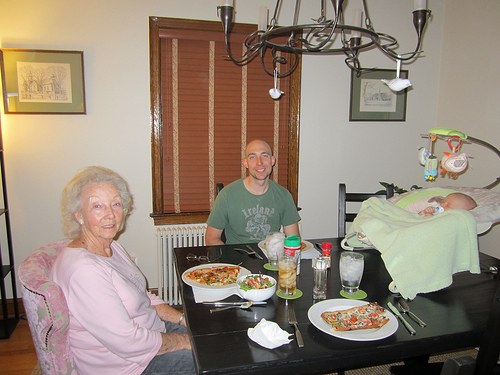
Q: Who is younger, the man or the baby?
A: The baby is younger than the man.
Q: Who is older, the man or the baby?
A: The man is older than the baby.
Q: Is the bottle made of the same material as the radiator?
A: No, the bottle is made of plastic and the radiator is made of metal.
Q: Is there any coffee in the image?
A: No, there is no coffee.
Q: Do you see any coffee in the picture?
A: No, there is no coffee.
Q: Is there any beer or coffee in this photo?
A: No, there are no coffee or beer.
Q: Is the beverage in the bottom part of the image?
A: Yes, the beverage is in the bottom of the image.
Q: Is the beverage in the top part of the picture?
A: No, the beverage is in the bottom of the image.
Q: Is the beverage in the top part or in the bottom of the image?
A: The beverage is in the bottom of the image.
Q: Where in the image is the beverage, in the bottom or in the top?
A: The beverage is in the bottom of the image.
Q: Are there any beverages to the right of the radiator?
A: Yes, there is a beverage to the right of the radiator.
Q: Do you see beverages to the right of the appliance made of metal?
A: Yes, there is a beverage to the right of the radiator.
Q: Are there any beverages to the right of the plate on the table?
A: Yes, there is a beverage to the right of the plate.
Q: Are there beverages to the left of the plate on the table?
A: No, the beverage is to the right of the plate.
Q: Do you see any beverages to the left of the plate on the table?
A: No, the beverage is to the right of the plate.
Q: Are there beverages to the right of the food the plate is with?
A: Yes, there is a beverage to the right of the food.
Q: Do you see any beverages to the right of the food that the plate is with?
A: Yes, there is a beverage to the right of the food.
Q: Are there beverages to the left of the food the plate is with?
A: No, the beverage is to the right of the food.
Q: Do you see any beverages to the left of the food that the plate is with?
A: No, the beverage is to the right of the food.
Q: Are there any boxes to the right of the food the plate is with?
A: No, there is a beverage to the right of the food.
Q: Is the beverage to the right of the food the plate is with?
A: Yes, the beverage is to the right of the food.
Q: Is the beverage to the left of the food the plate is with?
A: No, the beverage is to the right of the food.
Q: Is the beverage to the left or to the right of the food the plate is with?
A: The beverage is to the right of the food.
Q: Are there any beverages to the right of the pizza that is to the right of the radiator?
A: Yes, there is a beverage to the right of the pizza.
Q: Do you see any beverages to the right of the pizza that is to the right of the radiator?
A: Yes, there is a beverage to the right of the pizza.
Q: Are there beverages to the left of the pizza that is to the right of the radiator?
A: No, the beverage is to the right of the pizza.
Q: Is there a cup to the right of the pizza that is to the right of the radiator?
A: No, there is a beverage to the right of the pizza.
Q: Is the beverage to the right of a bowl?
A: Yes, the beverage is to the right of a bowl.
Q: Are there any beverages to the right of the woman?
A: Yes, there is a beverage to the right of the woman.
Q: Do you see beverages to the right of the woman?
A: Yes, there is a beverage to the right of the woman.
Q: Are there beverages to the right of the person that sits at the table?
A: Yes, there is a beverage to the right of the woman.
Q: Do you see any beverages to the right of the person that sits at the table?
A: Yes, there is a beverage to the right of the woman.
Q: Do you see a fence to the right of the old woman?
A: No, there is a beverage to the right of the woman.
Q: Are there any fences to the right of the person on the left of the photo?
A: No, there is a beverage to the right of the woman.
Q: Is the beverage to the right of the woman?
A: Yes, the beverage is to the right of the woman.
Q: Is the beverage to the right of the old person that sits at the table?
A: Yes, the beverage is to the right of the woman.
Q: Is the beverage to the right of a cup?
A: No, the beverage is to the right of the woman.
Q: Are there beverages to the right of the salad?
A: Yes, there is a beverage to the right of the salad.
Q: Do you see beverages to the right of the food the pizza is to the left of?
A: Yes, there is a beverage to the right of the salad.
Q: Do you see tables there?
A: Yes, there is a table.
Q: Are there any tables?
A: Yes, there is a table.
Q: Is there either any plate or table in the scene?
A: Yes, there is a table.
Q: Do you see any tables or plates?
A: Yes, there is a table.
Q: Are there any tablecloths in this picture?
A: No, there are no tablecloths.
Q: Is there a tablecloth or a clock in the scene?
A: No, there are no tablecloths or clocks.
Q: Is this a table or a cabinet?
A: This is a table.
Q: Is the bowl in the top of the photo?
A: No, the bowl is in the bottom of the image.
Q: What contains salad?
A: The bowl contains salad.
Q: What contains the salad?
A: The bowl contains salad.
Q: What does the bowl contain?
A: The bowl contains salad.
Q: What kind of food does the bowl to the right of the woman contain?
A: The bowl contains salad.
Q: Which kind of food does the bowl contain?
A: The bowl contains salad.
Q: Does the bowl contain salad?
A: Yes, the bowl contains salad.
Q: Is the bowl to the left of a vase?
A: No, the bowl is to the left of a beverage.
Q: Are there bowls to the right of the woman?
A: Yes, there is a bowl to the right of the woman.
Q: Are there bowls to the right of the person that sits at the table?
A: Yes, there is a bowl to the right of the woman.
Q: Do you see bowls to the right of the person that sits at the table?
A: Yes, there is a bowl to the right of the woman.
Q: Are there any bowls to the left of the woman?
A: No, the bowl is to the right of the woman.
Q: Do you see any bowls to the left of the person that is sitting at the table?
A: No, the bowl is to the right of the woman.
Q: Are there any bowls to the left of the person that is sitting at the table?
A: No, the bowl is to the right of the woman.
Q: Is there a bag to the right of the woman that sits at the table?
A: No, there is a bowl to the right of the woman.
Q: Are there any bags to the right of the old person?
A: No, there is a bowl to the right of the woman.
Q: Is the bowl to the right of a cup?
A: No, the bowl is to the right of the woman.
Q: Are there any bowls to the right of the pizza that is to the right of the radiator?
A: Yes, there is a bowl to the right of the pizza.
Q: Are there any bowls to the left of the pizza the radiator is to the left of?
A: No, the bowl is to the right of the pizza.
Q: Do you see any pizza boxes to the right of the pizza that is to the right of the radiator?
A: No, there is a bowl to the right of the pizza.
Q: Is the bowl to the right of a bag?
A: No, the bowl is to the right of the pizza.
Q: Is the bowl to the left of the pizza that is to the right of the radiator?
A: No, the bowl is to the right of the pizza.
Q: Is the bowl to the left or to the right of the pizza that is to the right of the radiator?
A: The bowl is to the right of the pizza.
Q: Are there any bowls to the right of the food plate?
A: Yes, there is a bowl to the right of the plate.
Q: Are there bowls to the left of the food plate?
A: No, the bowl is to the right of the plate.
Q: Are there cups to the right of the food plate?
A: No, there is a bowl to the right of the plate.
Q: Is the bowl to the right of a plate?
A: Yes, the bowl is to the right of a plate.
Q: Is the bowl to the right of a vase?
A: No, the bowl is to the right of a plate.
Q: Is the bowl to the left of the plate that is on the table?
A: No, the bowl is to the right of the plate.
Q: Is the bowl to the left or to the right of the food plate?
A: The bowl is to the right of the plate.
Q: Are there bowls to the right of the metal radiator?
A: Yes, there is a bowl to the right of the radiator.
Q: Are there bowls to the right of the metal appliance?
A: Yes, there is a bowl to the right of the radiator.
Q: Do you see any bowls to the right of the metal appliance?
A: Yes, there is a bowl to the right of the radiator.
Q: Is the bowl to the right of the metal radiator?
A: Yes, the bowl is to the right of the radiator.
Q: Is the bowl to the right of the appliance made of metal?
A: Yes, the bowl is to the right of the radiator.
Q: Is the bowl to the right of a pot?
A: No, the bowl is to the right of the radiator.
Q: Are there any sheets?
A: No, there are no sheets.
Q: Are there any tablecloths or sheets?
A: No, there are no sheets or tablecloths.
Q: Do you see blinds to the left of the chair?
A: Yes, there are blinds to the left of the chair.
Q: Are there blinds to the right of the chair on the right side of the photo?
A: No, the blinds are to the left of the chair.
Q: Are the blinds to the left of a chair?
A: Yes, the blinds are to the left of a chair.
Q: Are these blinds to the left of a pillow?
A: No, the blinds are to the left of a chair.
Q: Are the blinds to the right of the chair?
A: No, the blinds are to the left of the chair.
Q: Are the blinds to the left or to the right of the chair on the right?
A: The blinds are to the left of the chair.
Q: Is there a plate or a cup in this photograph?
A: Yes, there is a plate.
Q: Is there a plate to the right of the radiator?
A: Yes, there is a plate to the right of the radiator.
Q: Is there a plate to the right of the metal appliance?
A: Yes, there is a plate to the right of the radiator.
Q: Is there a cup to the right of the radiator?
A: No, there is a plate to the right of the radiator.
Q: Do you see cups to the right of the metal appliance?
A: No, there is a plate to the right of the radiator.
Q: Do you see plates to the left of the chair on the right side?
A: Yes, there is a plate to the left of the chair.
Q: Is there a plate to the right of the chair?
A: No, the plate is to the left of the chair.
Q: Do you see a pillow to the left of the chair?
A: No, there is a plate to the left of the chair.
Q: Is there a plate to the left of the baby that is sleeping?
A: Yes, there is a plate to the left of the baby.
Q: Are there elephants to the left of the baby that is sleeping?
A: No, there is a plate to the left of the baby.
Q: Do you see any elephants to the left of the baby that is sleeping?
A: No, there is a plate to the left of the baby.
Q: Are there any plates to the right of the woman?
A: Yes, there is a plate to the right of the woman.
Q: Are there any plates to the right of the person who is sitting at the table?
A: Yes, there is a plate to the right of the woman.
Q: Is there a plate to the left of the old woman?
A: No, the plate is to the right of the woman.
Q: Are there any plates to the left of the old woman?
A: No, the plate is to the right of the woman.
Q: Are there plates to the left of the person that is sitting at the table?
A: No, the plate is to the right of the woman.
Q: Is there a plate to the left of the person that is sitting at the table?
A: No, the plate is to the right of the woman.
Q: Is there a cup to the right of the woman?
A: No, there is a plate to the right of the woman.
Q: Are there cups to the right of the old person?
A: No, there is a plate to the right of the woman.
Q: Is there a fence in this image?
A: No, there are no fences.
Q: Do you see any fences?
A: No, there are no fences.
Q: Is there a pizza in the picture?
A: Yes, there is a pizza.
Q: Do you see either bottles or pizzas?
A: Yes, there is a pizza.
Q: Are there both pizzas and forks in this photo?
A: Yes, there are both a pizza and a fork.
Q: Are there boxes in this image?
A: No, there are no boxes.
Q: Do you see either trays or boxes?
A: No, there are no boxes or trays.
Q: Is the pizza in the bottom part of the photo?
A: Yes, the pizza is in the bottom of the image.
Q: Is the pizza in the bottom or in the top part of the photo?
A: The pizza is in the bottom of the image.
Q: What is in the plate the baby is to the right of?
A: The pizza is in the plate.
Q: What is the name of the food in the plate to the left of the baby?
A: The food is a pizza.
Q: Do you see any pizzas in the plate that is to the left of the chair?
A: Yes, there is a pizza in the plate.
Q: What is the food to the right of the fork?
A: The food is a pizza.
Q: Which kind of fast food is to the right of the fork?
A: The food is a pizza.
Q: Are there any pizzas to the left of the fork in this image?
A: No, the pizza is to the right of the fork.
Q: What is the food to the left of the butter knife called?
A: The food is a pizza.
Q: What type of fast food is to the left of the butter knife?
A: The food is a pizza.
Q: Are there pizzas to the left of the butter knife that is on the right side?
A: Yes, there is a pizza to the left of the butter knife.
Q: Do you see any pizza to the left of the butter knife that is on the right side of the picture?
A: Yes, there is a pizza to the left of the butter knife.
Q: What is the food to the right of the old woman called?
A: The food is a pizza.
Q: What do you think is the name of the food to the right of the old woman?
A: The food is a pizza.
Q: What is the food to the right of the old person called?
A: The food is a pizza.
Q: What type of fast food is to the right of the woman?
A: The food is a pizza.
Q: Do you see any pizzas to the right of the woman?
A: Yes, there is a pizza to the right of the woman.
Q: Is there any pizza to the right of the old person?
A: Yes, there is a pizza to the right of the woman.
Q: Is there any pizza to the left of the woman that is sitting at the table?
A: No, the pizza is to the right of the woman.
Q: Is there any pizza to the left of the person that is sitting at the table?
A: No, the pizza is to the right of the woman.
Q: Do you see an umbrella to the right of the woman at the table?
A: No, there is a pizza to the right of the woman.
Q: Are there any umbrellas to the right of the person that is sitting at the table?
A: No, there is a pizza to the right of the woman.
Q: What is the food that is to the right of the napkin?
A: The food is a pizza.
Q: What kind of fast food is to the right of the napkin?
A: The food is a pizza.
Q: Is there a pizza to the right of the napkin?
A: Yes, there is a pizza to the right of the napkin.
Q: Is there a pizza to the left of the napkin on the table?
A: No, the pizza is to the right of the napkin.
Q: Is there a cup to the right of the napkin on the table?
A: No, there is a pizza to the right of the napkin.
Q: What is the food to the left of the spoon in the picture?
A: The food is a pizza.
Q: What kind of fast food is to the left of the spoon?
A: The food is a pizza.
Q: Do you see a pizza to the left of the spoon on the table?
A: Yes, there is a pizza to the left of the spoon.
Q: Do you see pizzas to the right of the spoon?
A: No, the pizza is to the left of the spoon.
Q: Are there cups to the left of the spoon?
A: No, there is a pizza to the left of the spoon.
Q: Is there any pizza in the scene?
A: Yes, there is a pizza.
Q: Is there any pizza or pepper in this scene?
A: Yes, there is a pizza.